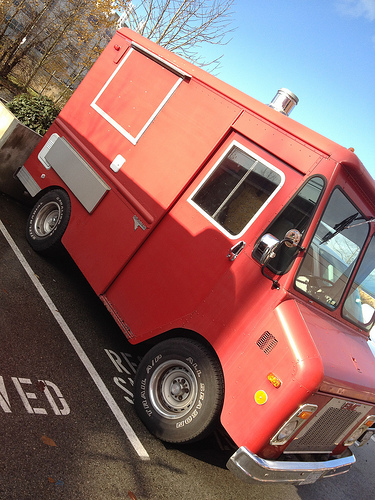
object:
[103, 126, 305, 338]
door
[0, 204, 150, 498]
parking space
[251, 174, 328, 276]
triangular panel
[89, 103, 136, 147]
trim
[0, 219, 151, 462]
whiteline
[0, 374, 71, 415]
writing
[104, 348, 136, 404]
writing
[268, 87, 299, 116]
spout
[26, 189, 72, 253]
black tire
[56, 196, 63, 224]
white writing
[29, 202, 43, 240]
white writing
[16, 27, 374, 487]
parked truck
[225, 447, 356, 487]
bumper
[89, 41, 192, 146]
opening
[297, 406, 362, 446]
front grill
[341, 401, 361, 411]
logo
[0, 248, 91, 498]
lot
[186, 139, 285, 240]
window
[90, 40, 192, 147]
white trim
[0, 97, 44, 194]
planter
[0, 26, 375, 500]
parking lot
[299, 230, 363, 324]
car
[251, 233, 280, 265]
mirror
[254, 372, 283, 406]
lights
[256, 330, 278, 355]
hole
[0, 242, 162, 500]
ground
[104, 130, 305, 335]
panels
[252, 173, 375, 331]
windows